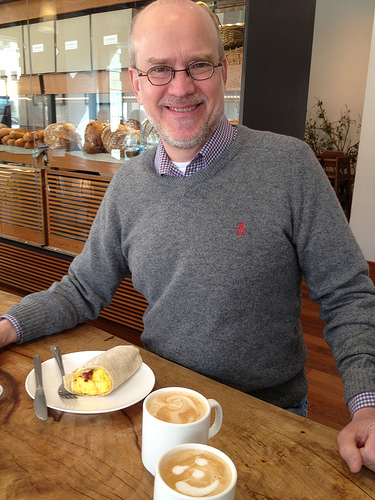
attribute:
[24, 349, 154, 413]
plate — White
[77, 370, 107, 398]
egg — scrambled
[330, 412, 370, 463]
hand — man's left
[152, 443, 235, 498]
coffee mug — coffee 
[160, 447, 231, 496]
drink — top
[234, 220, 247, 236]
logo — red 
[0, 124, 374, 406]
sweater — man's , natty gray, gray 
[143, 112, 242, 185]
plaid collar — purple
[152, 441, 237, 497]
mug — White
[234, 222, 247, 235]
logo — Red penguin 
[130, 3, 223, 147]
face — man's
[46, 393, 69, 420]
plate — edge 